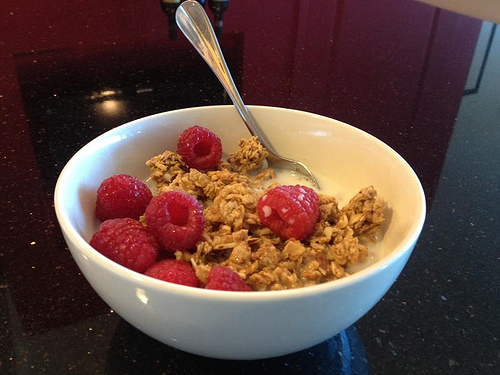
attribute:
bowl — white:
[53, 105, 428, 360]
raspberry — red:
[177, 126, 222, 170]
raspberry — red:
[145, 192, 204, 250]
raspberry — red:
[95, 175, 153, 220]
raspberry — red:
[90, 218, 158, 272]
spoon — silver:
[175, 0, 320, 192]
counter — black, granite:
[1, 2, 499, 374]